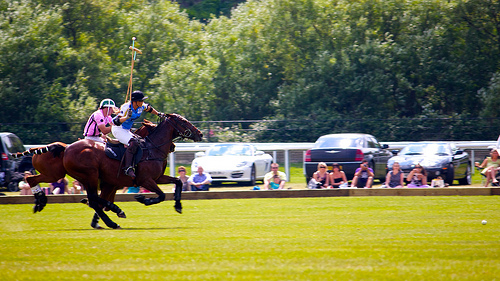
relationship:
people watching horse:
[18, 147, 500, 195] [67, 115, 195, 215]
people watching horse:
[18, 147, 500, 195] [19, 133, 67, 213]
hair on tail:
[9, 125, 70, 176] [7, 141, 82, 161]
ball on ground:
[481, 220, 487, 225] [5, 197, 497, 278]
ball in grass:
[481, 220, 487, 225] [204, 207, 316, 267]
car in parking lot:
[190, 143, 273, 185] [3, 136, 499, 176]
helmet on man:
[128, 87, 149, 101] [83, 91, 167, 178]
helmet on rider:
[98, 98, 118, 108] [81, 96, 136, 181]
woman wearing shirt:
[474, 143, 498, 192] [485, 156, 498, 171]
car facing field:
[190, 134, 472, 186] [7, 200, 499, 279]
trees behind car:
[5, 2, 499, 148] [190, 134, 472, 186]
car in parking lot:
[190, 134, 472, 186] [3, 173, 496, 203]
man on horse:
[83, 91, 167, 178] [19, 140, 69, 212]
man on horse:
[83, 91, 167, 178] [57, 114, 203, 234]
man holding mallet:
[83, 91, 167, 178] [123, 41, 142, 104]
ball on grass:
[479, 217, 489, 226] [315, 192, 448, 272]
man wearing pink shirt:
[83, 91, 167, 178] [78, 102, 115, 140]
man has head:
[83, 91, 167, 178] [100, 99, 115, 108]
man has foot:
[77, 90, 177, 191] [121, 162, 137, 182]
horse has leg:
[57, 114, 203, 234] [136, 177, 165, 208]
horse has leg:
[57, 114, 203, 234] [161, 173, 187, 216]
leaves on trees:
[1, 0, 498, 144] [251, 2, 429, 128]